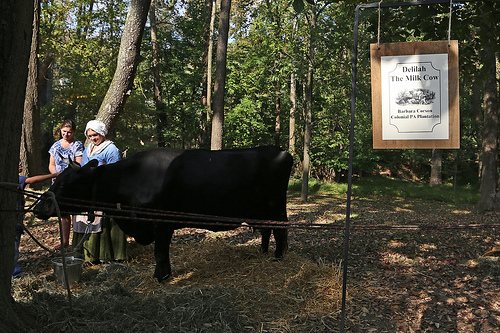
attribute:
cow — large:
[26, 137, 316, 281]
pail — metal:
[49, 255, 86, 287]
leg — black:
[154, 230, 174, 280]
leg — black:
[260, 225, 270, 250]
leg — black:
[277, 219, 289, 258]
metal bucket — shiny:
[52, 255, 85, 289]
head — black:
[31, 154, 103, 221]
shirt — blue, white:
[46, 140, 80, 174]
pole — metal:
[331, 0, 393, 322]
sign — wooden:
[368, 45, 460, 147]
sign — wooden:
[367, 38, 464, 151]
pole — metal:
[340, 4, 363, 330]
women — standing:
[33, 107, 113, 162]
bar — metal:
[338, 0, 432, 332]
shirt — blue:
[81, 139, 121, 166]